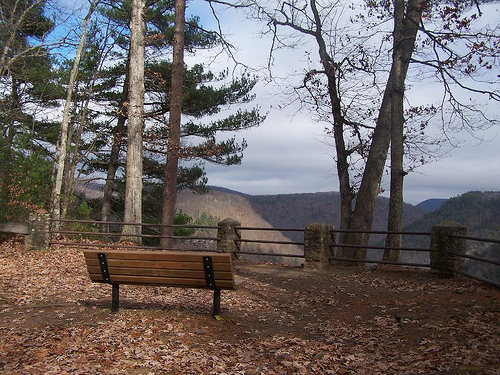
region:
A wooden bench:
[72, 237, 245, 314]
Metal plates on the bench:
[85, 252, 222, 286]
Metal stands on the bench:
[96, 281, 241, 310]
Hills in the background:
[186, 166, 333, 229]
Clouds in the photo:
[267, 125, 322, 172]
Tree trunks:
[343, 79, 415, 244]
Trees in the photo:
[47, 0, 217, 230]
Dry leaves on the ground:
[281, 290, 417, 365]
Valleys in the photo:
[265, 193, 418, 238]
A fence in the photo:
[250, 220, 436, 262]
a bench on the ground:
[26, 218, 316, 335]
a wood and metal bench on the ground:
[28, 191, 285, 326]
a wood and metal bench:
[32, 211, 289, 332]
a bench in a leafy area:
[62, 194, 300, 318]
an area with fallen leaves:
[7, 190, 410, 374]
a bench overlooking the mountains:
[62, 47, 460, 374]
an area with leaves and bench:
[23, 123, 467, 373]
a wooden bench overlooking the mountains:
[32, 161, 390, 358]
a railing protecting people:
[26, 134, 496, 326]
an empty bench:
[58, 169, 386, 361]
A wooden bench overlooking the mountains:
[25, 32, 442, 365]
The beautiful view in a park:
[41, 25, 471, 353]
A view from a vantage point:
[40, 2, 460, 352]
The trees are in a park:
[30, 32, 480, 360]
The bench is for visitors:
[16, 45, 461, 356]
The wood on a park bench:
[111, 253, 191, 279]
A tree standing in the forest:
[125, 143, 140, 218]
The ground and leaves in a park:
[267, 331, 362, 372]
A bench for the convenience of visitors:
[26, 212, 269, 352]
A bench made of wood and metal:
[17, 160, 359, 356]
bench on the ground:
[71, 240, 252, 320]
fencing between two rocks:
[247, 223, 300, 263]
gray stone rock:
[422, 213, 474, 280]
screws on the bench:
[89, 250, 114, 287]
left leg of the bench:
[110, 283, 125, 314]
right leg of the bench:
[208, 285, 228, 321]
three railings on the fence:
[247, 220, 291, 266]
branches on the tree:
[433, 65, 485, 155]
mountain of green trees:
[450, 186, 495, 221]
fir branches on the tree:
[185, 70, 264, 115]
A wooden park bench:
[83, 247, 244, 320]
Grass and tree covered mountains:
[61, 178, 497, 270]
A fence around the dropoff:
[48, 217, 498, 287]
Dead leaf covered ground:
[1, 231, 498, 370]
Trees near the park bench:
[7, 2, 255, 245]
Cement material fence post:
[430, 221, 465, 278]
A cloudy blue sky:
[0, 2, 497, 189]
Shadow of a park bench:
[78, 293, 231, 315]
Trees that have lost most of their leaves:
[217, 0, 497, 262]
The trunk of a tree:
[113, 0, 146, 250]